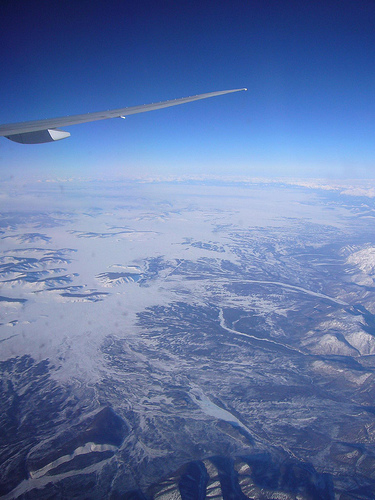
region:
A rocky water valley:
[54, 305, 165, 353]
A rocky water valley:
[182, 350, 255, 450]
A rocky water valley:
[273, 369, 373, 446]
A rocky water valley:
[192, 288, 284, 352]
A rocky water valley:
[12, 430, 146, 486]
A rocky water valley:
[4, 270, 64, 307]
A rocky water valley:
[292, 219, 370, 295]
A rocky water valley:
[11, 214, 110, 263]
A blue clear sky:
[267, 92, 373, 158]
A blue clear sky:
[19, 35, 160, 95]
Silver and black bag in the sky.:
[232, 75, 248, 99]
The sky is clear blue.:
[5, 7, 356, 177]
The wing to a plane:
[11, 78, 269, 151]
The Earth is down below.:
[28, 169, 354, 496]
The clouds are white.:
[27, 186, 211, 369]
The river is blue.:
[195, 293, 309, 364]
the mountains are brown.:
[307, 236, 372, 399]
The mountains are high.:
[315, 236, 373, 415]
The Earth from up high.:
[13, 159, 348, 495]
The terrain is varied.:
[12, 173, 372, 490]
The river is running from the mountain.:
[205, 289, 361, 407]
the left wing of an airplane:
[1, 79, 254, 150]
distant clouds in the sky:
[16, 156, 373, 203]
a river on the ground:
[210, 302, 293, 352]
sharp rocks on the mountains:
[150, 450, 341, 495]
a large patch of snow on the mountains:
[4, 200, 217, 390]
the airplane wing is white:
[1, 80, 253, 152]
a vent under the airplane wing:
[10, 126, 76, 146]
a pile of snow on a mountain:
[193, 392, 245, 432]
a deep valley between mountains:
[318, 346, 374, 370]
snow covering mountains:
[24, 240, 89, 306]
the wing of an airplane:
[2, 89, 252, 141]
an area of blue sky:
[260, 31, 342, 95]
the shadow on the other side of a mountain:
[334, 434, 365, 454]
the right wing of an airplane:
[0, 80, 264, 167]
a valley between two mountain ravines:
[222, 463, 241, 499]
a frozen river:
[219, 311, 258, 343]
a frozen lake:
[190, 381, 235, 426]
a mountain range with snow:
[312, 241, 373, 372]